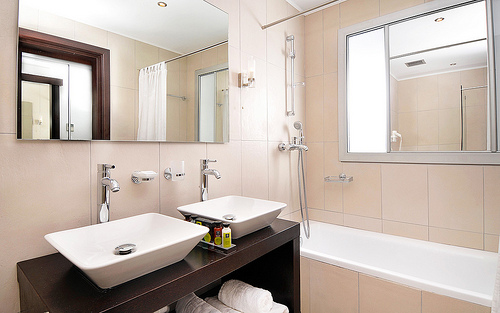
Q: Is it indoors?
A: Yes, it is indoors.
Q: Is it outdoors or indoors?
A: It is indoors.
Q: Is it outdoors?
A: No, it is indoors.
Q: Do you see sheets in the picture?
A: No, there are no sheets.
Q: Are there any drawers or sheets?
A: No, there are no sheets or drawers.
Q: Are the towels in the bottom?
A: Yes, the towels are in the bottom of the image.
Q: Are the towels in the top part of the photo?
A: No, the towels are in the bottom of the image.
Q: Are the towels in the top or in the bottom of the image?
A: The towels are in the bottom of the image.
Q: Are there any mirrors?
A: Yes, there is a mirror.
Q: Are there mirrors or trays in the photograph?
A: Yes, there is a mirror.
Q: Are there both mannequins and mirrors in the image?
A: No, there is a mirror but no mannequins.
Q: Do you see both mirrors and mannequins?
A: No, there is a mirror but no mannequins.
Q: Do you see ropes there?
A: No, there are no ropes.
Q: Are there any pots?
A: No, there are no pots.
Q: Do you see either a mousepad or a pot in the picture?
A: No, there are no pots or mouse pads.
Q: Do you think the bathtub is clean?
A: Yes, the bathtub is clean.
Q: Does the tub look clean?
A: Yes, the tub is clean.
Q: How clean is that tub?
A: The tub is clean.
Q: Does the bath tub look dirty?
A: No, the bath tub is clean.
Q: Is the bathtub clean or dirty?
A: The bathtub is clean.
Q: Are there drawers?
A: No, there are no drawers.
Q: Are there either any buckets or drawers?
A: No, there are no drawers or buckets.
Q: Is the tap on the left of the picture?
A: Yes, the tap is on the left of the image.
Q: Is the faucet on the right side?
A: No, the faucet is on the left of the image.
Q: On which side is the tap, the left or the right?
A: The tap is on the left of the image.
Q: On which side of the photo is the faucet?
A: The faucet is on the left of the image.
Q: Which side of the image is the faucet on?
A: The faucet is on the left of the image.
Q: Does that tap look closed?
A: Yes, the tap is closed.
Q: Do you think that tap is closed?
A: Yes, the tap is closed.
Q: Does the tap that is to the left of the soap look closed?
A: Yes, the tap is closed.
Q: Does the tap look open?
A: No, the tap is closed.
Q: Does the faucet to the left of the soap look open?
A: No, the tap is closed.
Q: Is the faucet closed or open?
A: The faucet is closed.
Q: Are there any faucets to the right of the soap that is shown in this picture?
A: No, the faucet is to the left of the soap.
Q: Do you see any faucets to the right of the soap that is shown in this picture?
A: No, the faucet is to the left of the soap.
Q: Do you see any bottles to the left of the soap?
A: No, there is a faucet to the left of the soap.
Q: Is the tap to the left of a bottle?
A: No, the tap is to the left of the soap.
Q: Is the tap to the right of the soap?
A: No, the tap is to the left of the soap.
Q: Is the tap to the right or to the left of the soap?
A: The tap is to the left of the soap.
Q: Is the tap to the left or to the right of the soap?
A: The tap is to the left of the soap.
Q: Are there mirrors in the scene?
A: Yes, there is a mirror.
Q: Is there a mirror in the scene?
A: Yes, there is a mirror.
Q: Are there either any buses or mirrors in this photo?
A: Yes, there is a mirror.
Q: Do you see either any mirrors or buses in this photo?
A: Yes, there is a mirror.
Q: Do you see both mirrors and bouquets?
A: No, there is a mirror but no bouquets.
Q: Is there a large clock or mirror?
A: Yes, there is a large mirror.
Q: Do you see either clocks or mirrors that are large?
A: Yes, the mirror is large.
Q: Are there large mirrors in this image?
A: Yes, there is a large mirror.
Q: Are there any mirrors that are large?
A: Yes, there is a mirror that is large.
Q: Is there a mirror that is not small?
A: Yes, there is a large mirror.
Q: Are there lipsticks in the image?
A: No, there are no lipsticks.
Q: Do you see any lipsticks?
A: No, there are no lipsticks.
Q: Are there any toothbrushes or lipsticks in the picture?
A: No, there are no lipsticks or toothbrushes.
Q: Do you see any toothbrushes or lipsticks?
A: No, there are no lipsticks or toothbrushes.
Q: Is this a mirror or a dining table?
A: This is a mirror.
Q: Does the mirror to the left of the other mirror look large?
A: Yes, the mirror is large.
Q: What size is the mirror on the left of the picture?
A: The mirror is large.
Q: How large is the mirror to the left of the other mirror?
A: The mirror is large.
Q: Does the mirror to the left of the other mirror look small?
A: No, the mirror is large.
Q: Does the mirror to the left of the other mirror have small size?
A: No, the mirror is large.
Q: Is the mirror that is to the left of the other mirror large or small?
A: The mirror is large.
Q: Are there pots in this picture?
A: No, there are no pots.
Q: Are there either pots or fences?
A: No, there are no pots or fences.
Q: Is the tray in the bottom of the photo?
A: Yes, the tray is in the bottom of the image.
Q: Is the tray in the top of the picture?
A: No, the tray is in the bottom of the image.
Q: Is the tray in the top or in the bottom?
A: The tray is in the bottom of the image.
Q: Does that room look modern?
A: Yes, the room is modern.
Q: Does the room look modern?
A: Yes, the room is modern.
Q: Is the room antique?
A: No, the room is modern.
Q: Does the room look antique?
A: No, the room is modern.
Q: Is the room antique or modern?
A: The room is modern.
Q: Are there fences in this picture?
A: No, there are no fences.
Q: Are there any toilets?
A: No, there are no toilets.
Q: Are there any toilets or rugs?
A: No, there are no toilets or rugs.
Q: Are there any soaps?
A: Yes, there is a soap.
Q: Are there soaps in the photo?
A: Yes, there is a soap.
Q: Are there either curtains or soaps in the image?
A: Yes, there is a soap.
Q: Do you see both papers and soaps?
A: No, there is a soap but no papers.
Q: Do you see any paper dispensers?
A: No, there are no paper dispensers.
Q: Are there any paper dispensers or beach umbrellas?
A: No, there are no paper dispensers or beach umbrellas.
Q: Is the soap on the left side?
A: Yes, the soap is on the left of the image.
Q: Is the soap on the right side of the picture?
A: No, the soap is on the left of the image.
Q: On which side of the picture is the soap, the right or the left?
A: The soap is on the left of the image.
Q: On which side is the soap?
A: The soap is on the left of the image.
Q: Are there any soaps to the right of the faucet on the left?
A: Yes, there is a soap to the right of the tap.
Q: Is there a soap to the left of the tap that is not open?
A: No, the soap is to the right of the tap.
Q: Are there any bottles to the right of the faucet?
A: No, there is a soap to the right of the faucet.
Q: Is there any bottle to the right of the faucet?
A: No, there is a soap to the right of the faucet.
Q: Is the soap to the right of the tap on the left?
A: Yes, the soap is to the right of the tap.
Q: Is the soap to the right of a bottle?
A: No, the soap is to the right of the tap.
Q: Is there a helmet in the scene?
A: No, there are no helmets.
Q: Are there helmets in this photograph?
A: No, there are no helmets.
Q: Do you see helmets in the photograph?
A: No, there are no helmets.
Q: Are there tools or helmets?
A: No, there are no helmets or tools.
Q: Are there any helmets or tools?
A: No, there are no helmets or tools.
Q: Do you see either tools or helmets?
A: No, there are no helmets or tools.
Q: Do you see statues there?
A: No, there are no statues.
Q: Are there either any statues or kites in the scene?
A: No, there are no statues or kites.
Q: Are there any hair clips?
A: No, there are no hair clips.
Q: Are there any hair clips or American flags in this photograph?
A: No, there are no hair clips or American flags.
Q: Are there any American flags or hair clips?
A: No, there are no hair clips or American flags.